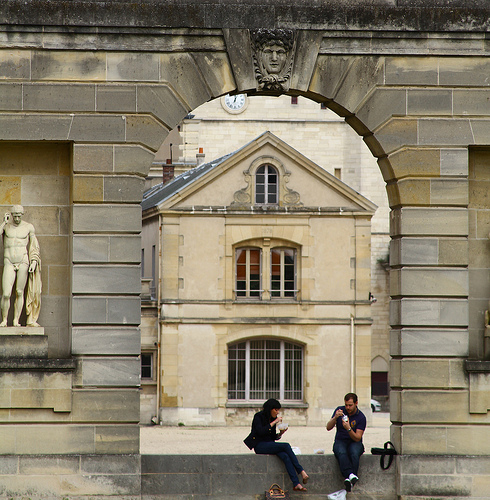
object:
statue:
[0, 204, 41, 328]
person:
[243, 398, 309, 492]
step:
[143, 449, 394, 496]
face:
[261, 46, 288, 75]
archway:
[134, 86, 412, 491]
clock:
[220, 95, 250, 115]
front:
[145, 90, 376, 430]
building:
[139, 130, 377, 429]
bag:
[370, 441, 397, 470]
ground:
[137, 424, 390, 447]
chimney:
[162, 159, 176, 184]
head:
[11, 204, 24, 225]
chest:
[5, 229, 27, 239]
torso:
[3, 227, 29, 264]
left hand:
[28, 263, 36, 273]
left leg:
[13, 270, 29, 321]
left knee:
[15, 287, 23, 296]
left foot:
[13, 321, 21, 327]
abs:
[6, 241, 26, 255]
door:
[371, 371, 389, 396]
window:
[227, 342, 307, 399]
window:
[232, 243, 300, 290]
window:
[253, 163, 279, 204]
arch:
[140, 130, 379, 209]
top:
[0, 1, 490, 87]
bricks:
[346, 61, 485, 111]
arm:
[29, 231, 40, 263]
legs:
[0, 265, 30, 321]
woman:
[263, 398, 282, 418]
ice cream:
[277, 423, 288, 431]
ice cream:
[342, 415, 349, 421]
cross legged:
[254, 442, 309, 492]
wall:
[0, 384, 113, 497]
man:
[327, 393, 367, 491]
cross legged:
[333, 440, 365, 486]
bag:
[323, 486, 346, 498]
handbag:
[255, 482, 288, 498]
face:
[345, 400, 354, 413]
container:
[277, 422, 288, 430]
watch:
[346, 428, 352, 433]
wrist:
[346, 427, 353, 432]